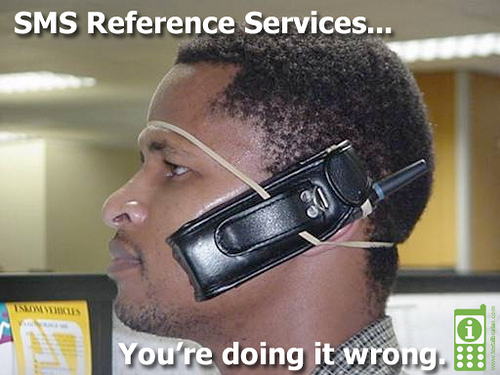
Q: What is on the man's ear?
A: A cell phone.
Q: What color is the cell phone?
A: Black.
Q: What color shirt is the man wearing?
A: Black and white.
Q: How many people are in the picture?
A: One.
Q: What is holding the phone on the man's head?
A: A rubber band.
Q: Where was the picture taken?
A: In an office.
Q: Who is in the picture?
A: A man.